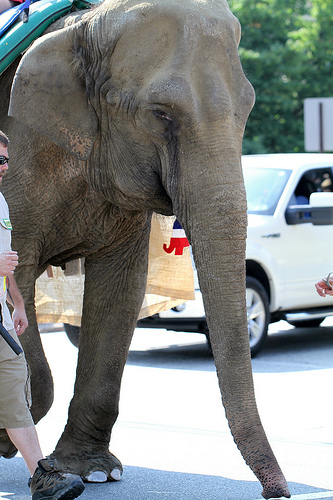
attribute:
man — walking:
[0, 126, 20, 306]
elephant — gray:
[18, 22, 267, 252]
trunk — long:
[195, 188, 292, 498]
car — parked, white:
[167, 126, 331, 338]